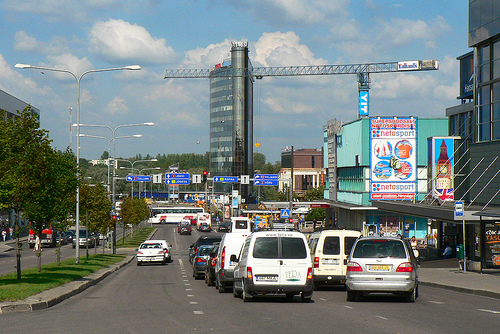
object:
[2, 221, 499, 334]
street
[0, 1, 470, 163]
sky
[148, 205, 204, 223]
bus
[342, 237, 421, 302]
van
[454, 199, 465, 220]
sign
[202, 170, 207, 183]
traffic light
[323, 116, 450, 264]
building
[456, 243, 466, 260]
trash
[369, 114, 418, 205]
ad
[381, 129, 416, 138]
netosport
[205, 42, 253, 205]
building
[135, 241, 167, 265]
car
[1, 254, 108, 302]
grass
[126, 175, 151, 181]
sign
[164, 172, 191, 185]
signs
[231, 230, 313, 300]
van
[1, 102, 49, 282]
trees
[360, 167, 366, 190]
windows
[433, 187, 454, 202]
flag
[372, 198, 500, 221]
awning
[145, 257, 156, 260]
license plate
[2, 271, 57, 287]
shadows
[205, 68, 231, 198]
side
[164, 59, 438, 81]
crane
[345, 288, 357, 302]
wheels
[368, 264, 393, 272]
license plate